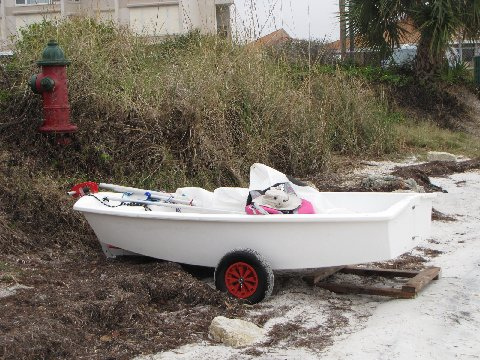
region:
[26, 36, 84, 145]
red and green fire hydrant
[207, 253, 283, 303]
red and black tire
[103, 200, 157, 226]
black chains on boat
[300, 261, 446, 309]
brown wood plank under boat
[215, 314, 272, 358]
white boulder near tire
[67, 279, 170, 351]
brown dirt near boat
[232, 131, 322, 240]
pink and white item in boat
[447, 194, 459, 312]
sand near beach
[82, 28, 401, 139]
hill with multiple growing plants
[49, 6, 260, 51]
white house with white garages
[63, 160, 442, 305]
small white boat on the shore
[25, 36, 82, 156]
red and green fire hydrant in the grass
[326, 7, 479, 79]
white house on the beach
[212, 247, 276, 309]
black tire with red rims on boat trailer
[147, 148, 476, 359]
white sandy shoreline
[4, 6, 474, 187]
small slope covered in weed and grass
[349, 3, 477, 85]
palm tree on the hill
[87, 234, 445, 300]
boat trailer laying in the sand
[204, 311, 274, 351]
large white rock on the beach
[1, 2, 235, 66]
large cement building on the hill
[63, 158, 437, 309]
a dingy is on wheels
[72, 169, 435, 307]
the dingy is white and has red wheels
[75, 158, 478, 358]
the dingy is on a beach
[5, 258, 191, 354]
seaweed is piled on the beach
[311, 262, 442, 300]
a wooden pallet is under the boat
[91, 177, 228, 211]
metal poles are in the boat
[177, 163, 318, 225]
plastic tarp is stuffed into the boat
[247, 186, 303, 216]
a beige hat is in the boat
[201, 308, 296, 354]
a rock is on the beach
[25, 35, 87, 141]
a fire hydrant is on the bank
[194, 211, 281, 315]
boat on wheels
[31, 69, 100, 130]
red on the bottom of fire hydrant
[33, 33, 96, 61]
green on top fire hydrant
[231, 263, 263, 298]
center of wheel is red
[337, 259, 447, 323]
wood under the boat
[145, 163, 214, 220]
poles in the boat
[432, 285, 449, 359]
snow on the ground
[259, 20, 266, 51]
roof is a tan color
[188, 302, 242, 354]
rock next to the boat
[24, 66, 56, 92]
green on openings of fire hydrant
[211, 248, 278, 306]
black snow covered tire with red rim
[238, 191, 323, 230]
pink stuff inside boat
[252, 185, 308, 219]
white hat on top of pink stuff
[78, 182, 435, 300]
white boat with wheels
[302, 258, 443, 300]
wooden frame on the ground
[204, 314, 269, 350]
white rock on the ground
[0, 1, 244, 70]
house in the background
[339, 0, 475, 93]
bottom of a palm tree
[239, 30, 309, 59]
top of a roof